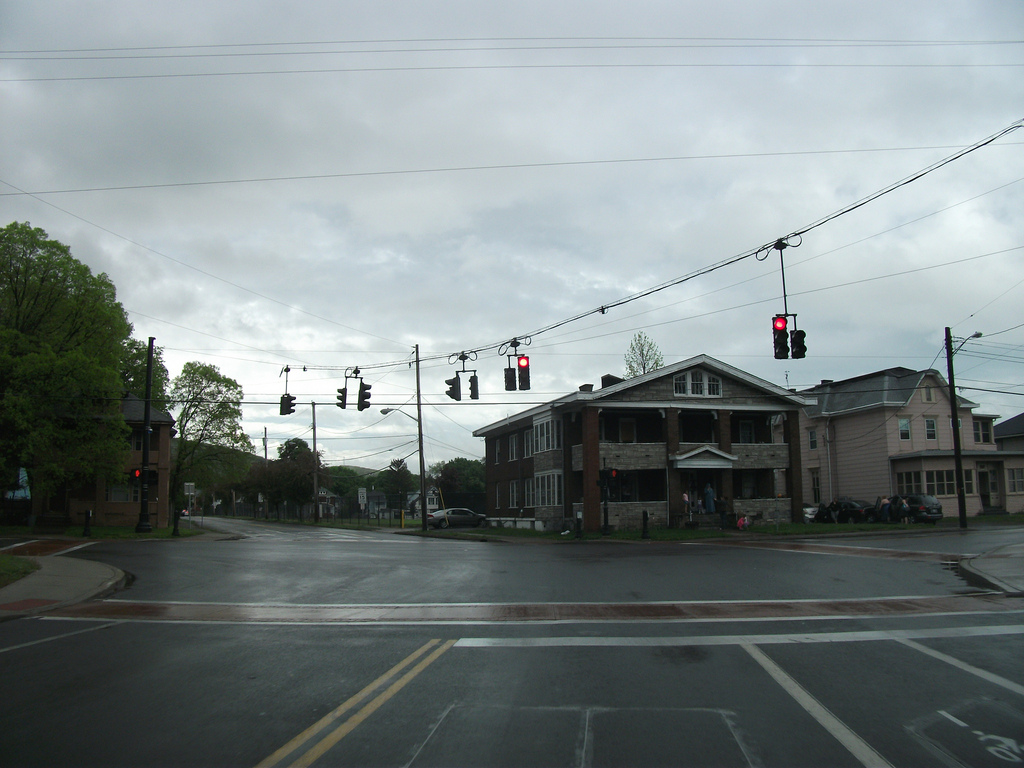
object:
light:
[517, 356, 530, 390]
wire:
[0, 143, 1024, 195]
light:
[772, 317, 789, 360]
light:
[789, 330, 806, 360]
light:
[504, 367, 517, 389]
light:
[469, 376, 478, 398]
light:
[444, 375, 460, 401]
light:
[358, 383, 372, 411]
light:
[280, 393, 296, 414]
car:
[427, 508, 487, 529]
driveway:
[373, 527, 485, 534]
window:
[603, 417, 636, 443]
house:
[473, 353, 820, 531]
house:
[770, 367, 1024, 518]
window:
[898, 418, 911, 440]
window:
[925, 418, 938, 440]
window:
[532, 419, 560, 453]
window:
[534, 469, 564, 506]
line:
[740, 644, 899, 767]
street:
[0, 516, 1024, 768]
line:
[454, 625, 1024, 647]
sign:
[184, 482, 195, 530]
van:
[860, 494, 943, 526]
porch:
[670, 445, 742, 530]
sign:
[358, 488, 367, 531]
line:
[252, 639, 457, 768]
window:
[673, 367, 723, 397]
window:
[920, 380, 936, 404]